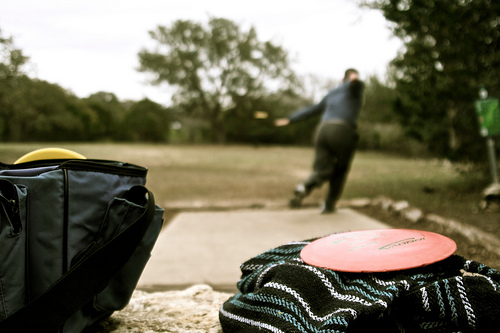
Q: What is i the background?
A: Trees.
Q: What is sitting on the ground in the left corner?
A: Black bag.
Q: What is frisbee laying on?
A: A sweater.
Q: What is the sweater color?
A: Black, blue, green stripe.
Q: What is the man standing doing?
A: Throwing a frisbee.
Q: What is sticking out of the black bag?
A: A yellow frisbee.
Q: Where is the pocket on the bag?
A: Front.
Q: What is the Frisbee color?
A: Orange.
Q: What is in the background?
A: Trees.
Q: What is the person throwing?
A: Frisbee.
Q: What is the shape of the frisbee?
A: Disk.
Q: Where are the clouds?
A: Sky.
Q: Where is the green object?
A: Right.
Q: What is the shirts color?
A: Blue.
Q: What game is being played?
A: Frisbee.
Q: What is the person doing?
A: Throwing.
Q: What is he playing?
A: Frisbee golf.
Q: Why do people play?
A: Fun competition.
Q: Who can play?
A: Anyone who can toss a disc.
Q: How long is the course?
A: Varies.